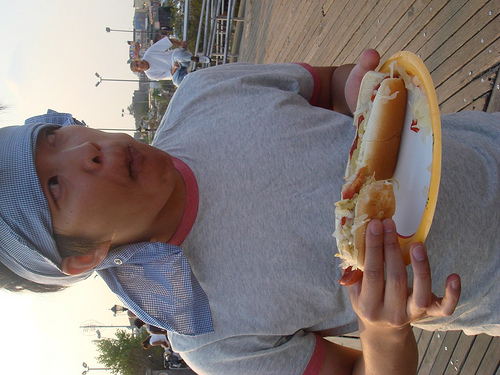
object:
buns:
[331, 78, 410, 274]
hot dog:
[341, 171, 366, 199]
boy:
[1, 50, 497, 374]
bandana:
[0, 109, 215, 336]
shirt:
[148, 62, 500, 375]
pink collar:
[171, 158, 199, 245]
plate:
[374, 50, 442, 266]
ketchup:
[371, 74, 391, 102]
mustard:
[346, 116, 368, 179]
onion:
[332, 225, 354, 271]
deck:
[237, 0, 499, 374]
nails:
[371, 222, 383, 235]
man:
[130, 36, 211, 88]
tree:
[92, 329, 165, 374]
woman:
[142, 333, 172, 351]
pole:
[99, 79, 169, 82]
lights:
[95, 81, 100, 87]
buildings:
[129, 88, 148, 117]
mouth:
[125, 147, 145, 182]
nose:
[64, 141, 103, 172]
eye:
[45, 130, 57, 146]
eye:
[47, 175, 62, 202]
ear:
[61, 239, 110, 276]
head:
[16, 125, 174, 273]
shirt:
[143, 35, 176, 82]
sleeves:
[196, 337, 324, 375]